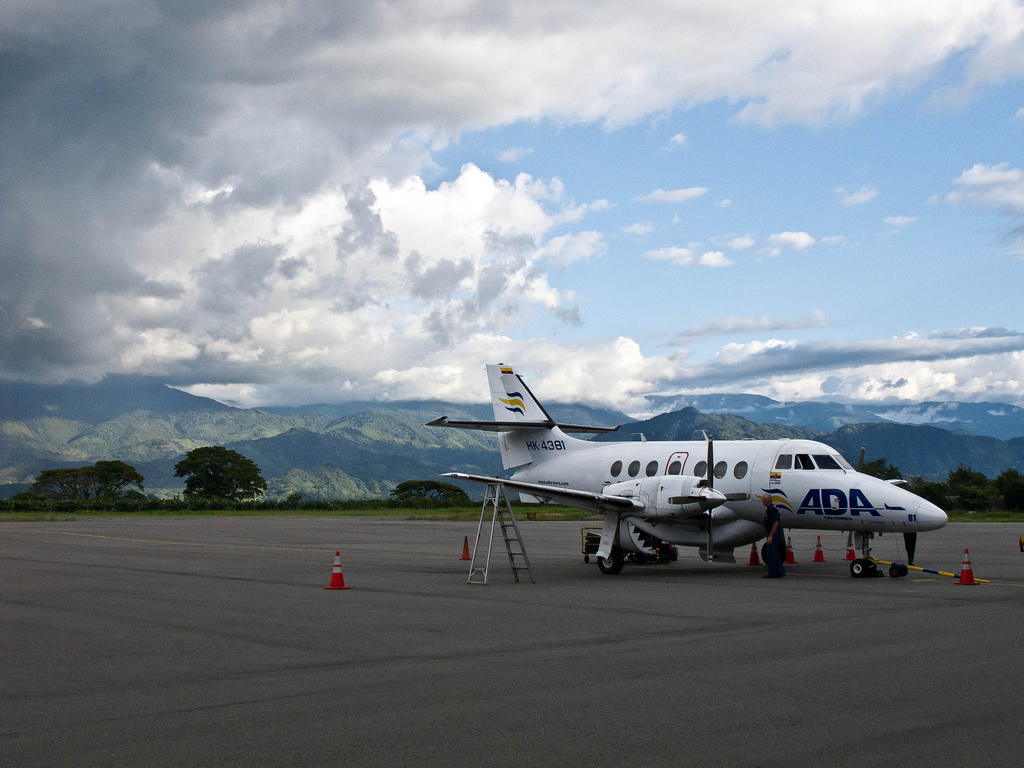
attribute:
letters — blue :
[781, 474, 892, 529]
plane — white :
[355, 318, 978, 597]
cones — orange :
[299, 513, 989, 602]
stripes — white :
[325, 538, 989, 582]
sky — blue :
[9, 5, 1016, 459]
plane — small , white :
[381, 325, 982, 565]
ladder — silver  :
[459, 476, 563, 591]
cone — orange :
[308, 532, 352, 587]